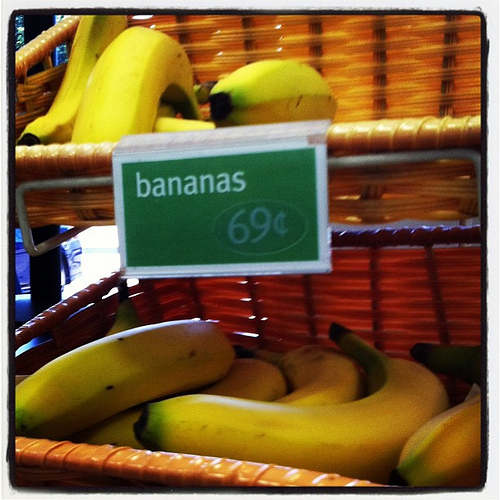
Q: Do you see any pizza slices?
A: No, there are no pizza slices.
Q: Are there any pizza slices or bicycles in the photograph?
A: No, there are no pizza slices or bicycles.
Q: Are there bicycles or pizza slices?
A: No, there are no pizza slices or bicycles.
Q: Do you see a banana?
A: Yes, there are bananas.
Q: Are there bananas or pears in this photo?
A: Yes, there are bananas.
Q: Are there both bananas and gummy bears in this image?
A: No, there are bananas but no gummy bears.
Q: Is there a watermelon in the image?
A: No, there are no watermelons.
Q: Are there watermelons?
A: No, there are no watermelons.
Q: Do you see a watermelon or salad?
A: No, there are no watermelons or salad.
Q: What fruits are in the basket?
A: The fruits are bananas.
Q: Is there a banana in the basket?
A: Yes, there are bananas in the basket.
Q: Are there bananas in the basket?
A: Yes, there are bananas in the basket.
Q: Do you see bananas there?
A: Yes, there is a banana.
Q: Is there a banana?
A: Yes, there is a banana.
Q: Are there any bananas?
A: Yes, there is a banana.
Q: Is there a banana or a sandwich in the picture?
A: Yes, there is a banana.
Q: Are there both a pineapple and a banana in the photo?
A: No, there is a banana but no pineapples.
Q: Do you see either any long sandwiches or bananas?
A: Yes, there is a long banana.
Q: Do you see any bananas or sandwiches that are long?
A: Yes, the banana is long.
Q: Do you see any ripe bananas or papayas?
A: Yes, there is a ripe banana.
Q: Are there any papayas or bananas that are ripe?
A: Yes, the banana is ripe.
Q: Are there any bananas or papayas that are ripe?
A: Yes, the banana is ripe.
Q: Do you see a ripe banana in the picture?
A: Yes, there is a ripe banana.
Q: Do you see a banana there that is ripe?
A: Yes, there is a banana that is ripe.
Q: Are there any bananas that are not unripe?
A: Yes, there is an ripe banana.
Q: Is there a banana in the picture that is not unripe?
A: Yes, there is an ripe banana.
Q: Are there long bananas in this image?
A: Yes, there is a long banana.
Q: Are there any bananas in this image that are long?
A: Yes, there is a banana that is long.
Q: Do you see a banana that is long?
A: Yes, there is a banana that is long.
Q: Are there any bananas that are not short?
A: Yes, there is a long banana.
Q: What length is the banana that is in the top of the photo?
A: The banana is long.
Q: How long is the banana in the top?
A: The banana is long.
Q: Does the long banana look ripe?
A: Yes, the banana is ripe.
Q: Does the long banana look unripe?
A: No, the banana is ripe.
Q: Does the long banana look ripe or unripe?
A: The banana is ripe.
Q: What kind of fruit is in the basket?
A: The fruit is a banana.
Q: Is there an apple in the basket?
A: No, there is a banana in the basket.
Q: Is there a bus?
A: No, there are no buses.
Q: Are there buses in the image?
A: No, there are no buses.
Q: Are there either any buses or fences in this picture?
A: No, there are no buses or fences.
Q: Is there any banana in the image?
A: Yes, there is a banana.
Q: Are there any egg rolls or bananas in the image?
A: Yes, there is a banana.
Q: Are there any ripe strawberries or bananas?
A: Yes, there is a ripe banana.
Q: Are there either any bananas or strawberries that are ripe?
A: Yes, the banana is ripe.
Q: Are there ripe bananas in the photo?
A: Yes, there is a ripe banana.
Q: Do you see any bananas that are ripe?
A: Yes, there is a ripe banana.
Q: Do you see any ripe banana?
A: Yes, there is a ripe banana.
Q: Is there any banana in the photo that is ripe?
A: Yes, there is a banana that is ripe.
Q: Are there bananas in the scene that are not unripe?
A: Yes, there is an ripe banana.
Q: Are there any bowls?
A: No, there are no bowls.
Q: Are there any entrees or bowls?
A: No, there are no bowls or entrees.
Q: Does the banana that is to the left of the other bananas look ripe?
A: Yes, the banana is ripe.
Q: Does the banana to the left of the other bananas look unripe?
A: No, the banana is ripe.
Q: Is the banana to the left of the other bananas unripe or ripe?
A: The banana is ripe.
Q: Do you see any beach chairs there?
A: No, there are no beach chairs.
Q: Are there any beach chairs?
A: No, there are no beach chairs.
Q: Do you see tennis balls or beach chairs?
A: No, there are no beach chairs or tennis balls.